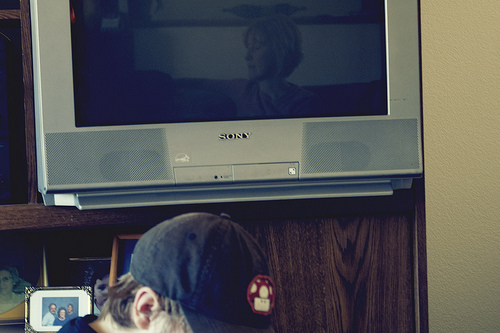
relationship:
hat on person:
[143, 224, 271, 315] [83, 254, 156, 319]